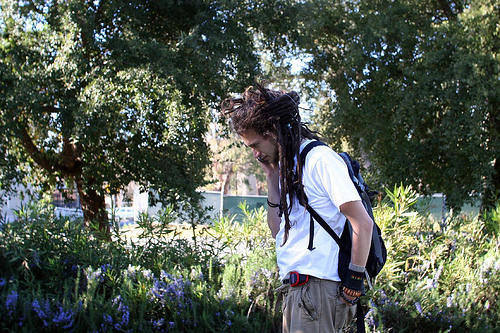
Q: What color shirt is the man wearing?
A: White.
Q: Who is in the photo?
A: A man.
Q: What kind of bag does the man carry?
A: A backpack.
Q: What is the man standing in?
A: A field.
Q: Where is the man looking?
A: Down at the ground.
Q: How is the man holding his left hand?
A: In his back pocket.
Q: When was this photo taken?
A: During the day.